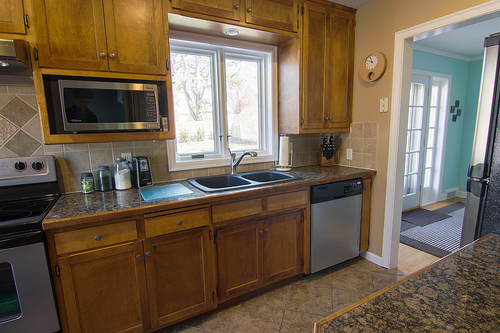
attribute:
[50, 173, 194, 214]
counter — marble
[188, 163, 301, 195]
sink — double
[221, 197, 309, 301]
cabinets — brown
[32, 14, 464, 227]
kitchen — empty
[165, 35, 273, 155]
window — closed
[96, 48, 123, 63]
knobs — silver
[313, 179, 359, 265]
dishwasher — steel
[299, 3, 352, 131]
cabinets — long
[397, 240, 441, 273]
floor — wood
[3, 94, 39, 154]
tile — backsplash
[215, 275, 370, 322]
floor — tile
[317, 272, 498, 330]
counter — granite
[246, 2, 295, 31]
cabinet — closed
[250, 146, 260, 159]
tap — closed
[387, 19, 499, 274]
door — open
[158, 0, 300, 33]
shelves — wooden